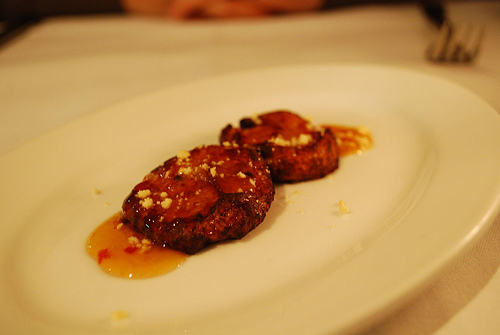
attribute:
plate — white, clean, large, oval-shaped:
[1, 62, 499, 334]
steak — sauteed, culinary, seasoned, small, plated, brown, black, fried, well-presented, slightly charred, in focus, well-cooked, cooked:
[121, 109, 339, 254]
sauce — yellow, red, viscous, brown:
[84, 107, 373, 282]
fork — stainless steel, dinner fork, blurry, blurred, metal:
[417, 0, 486, 64]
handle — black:
[417, 0, 448, 25]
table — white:
[1, 3, 499, 335]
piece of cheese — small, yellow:
[338, 199, 348, 213]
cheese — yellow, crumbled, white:
[92, 114, 352, 241]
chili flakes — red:
[94, 108, 305, 263]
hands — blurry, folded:
[122, 0, 323, 22]